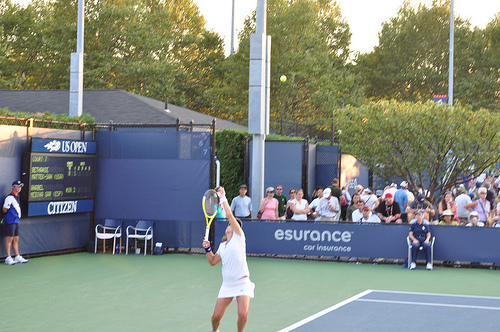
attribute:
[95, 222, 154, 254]
chairs — empty, blue, white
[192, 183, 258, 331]
tennis player — female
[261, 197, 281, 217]
top — pink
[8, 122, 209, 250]
fence — surrounding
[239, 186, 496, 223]
spectators — watching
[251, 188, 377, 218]
people — watching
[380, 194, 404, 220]
man — watching, sitting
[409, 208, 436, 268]
referee — sitting, watching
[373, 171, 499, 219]
audience — watching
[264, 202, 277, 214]
shirt — pink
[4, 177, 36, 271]
ballboy — standing